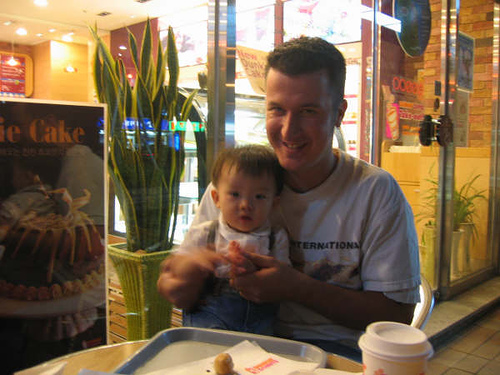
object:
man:
[156, 34, 420, 363]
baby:
[173, 142, 293, 338]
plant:
[86, 14, 199, 343]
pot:
[105, 241, 185, 343]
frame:
[368, 0, 499, 308]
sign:
[0, 96, 111, 366]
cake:
[0, 172, 107, 344]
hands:
[227, 247, 298, 304]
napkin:
[146, 337, 363, 374]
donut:
[212, 350, 237, 374]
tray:
[110, 324, 380, 375]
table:
[7, 337, 393, 375]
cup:
[357, 319, 434, 375]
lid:
[355, 318, 435, 360]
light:
[0, 2, 138, 85]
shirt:
[181, 144, 424, 342]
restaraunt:
[0, 0, 500, 375]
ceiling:
[0, 0, 212, 46]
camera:
[207, 34, 368, 228]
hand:
[156, 234, 272, 305]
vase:
[418, 223, 467, 290]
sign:
[378, 0, 486, 156]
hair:
[211, 143, 287, 196]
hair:
[263, 33, 347, 123]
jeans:
[181, 279, 279, 340]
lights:
[33, 0, 52, 9]